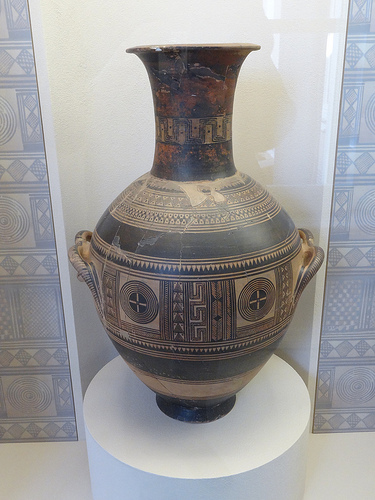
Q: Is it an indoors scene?
A: Yes, it is indoors.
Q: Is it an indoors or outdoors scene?
A: It is indoors.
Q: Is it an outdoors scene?
A: No, it is indoors.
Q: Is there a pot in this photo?
A: Yes, there is a pot.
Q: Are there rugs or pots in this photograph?
A: Yes, there is a pot.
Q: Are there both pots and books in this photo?
A: No, there is a pot but no books.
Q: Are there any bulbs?
A: No, there are no bulbs.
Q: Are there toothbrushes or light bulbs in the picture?
A: No, there are no light bulbs or toothbrushes.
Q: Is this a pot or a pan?
A: This is a pot.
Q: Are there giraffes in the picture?
A: No, there are no giraffes.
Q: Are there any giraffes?
A: No, there are no giraffes.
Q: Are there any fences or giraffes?
A: No, there are no giraffes or fences.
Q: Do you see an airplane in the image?
A: No, there are no airplanes.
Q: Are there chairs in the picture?
A: No, there are no chairs.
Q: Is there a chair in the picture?
A: No, there are no chairs.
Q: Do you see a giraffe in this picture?
A: No, there are no giraffes.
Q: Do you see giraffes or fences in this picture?
A: No, there are no giraffes or fences.